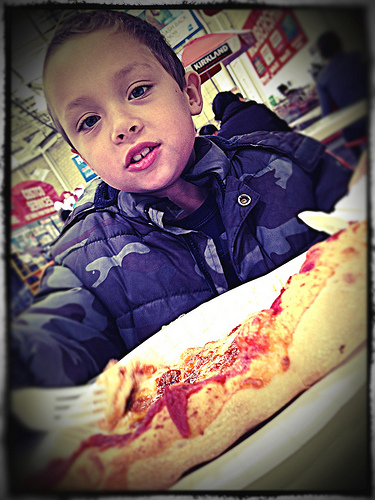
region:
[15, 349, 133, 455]
a fork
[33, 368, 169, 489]
a fork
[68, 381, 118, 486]
a fork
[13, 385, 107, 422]
the white fork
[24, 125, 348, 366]
the boy's jacket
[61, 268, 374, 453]
the pizza on the plate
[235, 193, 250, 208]
the button snap on the jacket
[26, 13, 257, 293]
the boy looking at the camera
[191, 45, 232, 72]
the word KIRKLAND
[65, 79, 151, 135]
the boy's eyes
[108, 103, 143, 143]
the boy's nose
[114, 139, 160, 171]
the boy's opened mouth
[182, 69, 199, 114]
the boy's left ear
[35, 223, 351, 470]
large piece of pizza pie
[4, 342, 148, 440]
plastic fork for eating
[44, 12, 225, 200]
little boy with short brown hair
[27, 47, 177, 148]
little boy with big brown eyes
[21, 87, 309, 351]
young boy wearing blue jacket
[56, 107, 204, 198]
young boy with two big front teeth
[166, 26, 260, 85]
advertisement with the letter k on it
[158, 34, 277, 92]
advertisement with the letterion it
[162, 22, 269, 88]
advertisement with the letter l on it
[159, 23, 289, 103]
advertisement with the letter a on it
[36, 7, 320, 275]
The boy has hair.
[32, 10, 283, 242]
Boy's hair is short.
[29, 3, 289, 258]
Boy's hair is neat.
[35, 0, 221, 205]
Boy's hair is tidy.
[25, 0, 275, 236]
Boy's hair is groomed.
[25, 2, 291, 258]
Boy's hair is brown.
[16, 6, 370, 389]
Boy is wearing jacket.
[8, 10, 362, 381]
Jacket has camo design.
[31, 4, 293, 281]
The boy has teeth.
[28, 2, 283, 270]
The boy has eyes.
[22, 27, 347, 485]
the boy wearing a jacket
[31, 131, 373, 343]
the jacket is blue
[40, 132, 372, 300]
the jacket is camouflage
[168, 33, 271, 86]
the umbrella behind the boy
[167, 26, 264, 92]
the umbrella is open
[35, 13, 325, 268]
the boy holding a fork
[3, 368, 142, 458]
the fork is plastic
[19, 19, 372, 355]
the boy eating pizza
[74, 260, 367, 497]
the crust of the pizza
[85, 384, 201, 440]
tomato sauce on the pizza